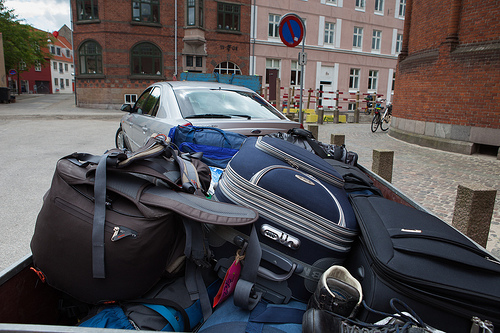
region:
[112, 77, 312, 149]
The gray vehicle in front of the bags.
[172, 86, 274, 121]
The back window of the vehicle.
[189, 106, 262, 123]
The windshield wiper on the back window of the vehicle.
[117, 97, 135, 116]
The side view mirror of the vehicle.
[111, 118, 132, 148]
The front tire of the vehicle.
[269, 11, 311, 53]
The circle sign to the right of the vehicle.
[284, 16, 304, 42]
The blue color within the circle street sign.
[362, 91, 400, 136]
The bicycle on the right.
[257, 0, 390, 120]
The light pink building.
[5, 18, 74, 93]
The red buildings in the distance.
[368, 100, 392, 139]
the parked bicycle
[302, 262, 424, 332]
the pair of shoes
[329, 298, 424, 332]
the shoe laces on the shoes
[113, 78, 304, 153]
the silver car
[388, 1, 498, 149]
the red brick building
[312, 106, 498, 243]
the stone sidewalk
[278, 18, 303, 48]
a red and blue circle sign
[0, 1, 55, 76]
the tree in the distance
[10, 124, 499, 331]
a pile of bags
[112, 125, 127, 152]
the front wheel on the car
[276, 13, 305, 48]
A blue and red sign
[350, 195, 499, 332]
A black suitcase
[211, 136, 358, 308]
A blue and grey suitcase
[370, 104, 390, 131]
A bicycle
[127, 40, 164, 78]
A green framed window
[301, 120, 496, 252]
A paved brick sidewalk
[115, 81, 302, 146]
A silver car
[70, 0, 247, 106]
A brick building with many windows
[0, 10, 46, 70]
A green leafy tree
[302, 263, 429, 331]
A pair of black shoes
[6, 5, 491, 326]
A city street scene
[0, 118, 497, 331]
A cart of luggage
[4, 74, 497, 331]
The car is pulling the cart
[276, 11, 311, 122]
A street sign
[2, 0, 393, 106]
Buildings are across the street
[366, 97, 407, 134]
A bicycle is next to the building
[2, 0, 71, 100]
A tree is growing near the building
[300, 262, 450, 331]
A pair of shoes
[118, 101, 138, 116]
The car's side view mirror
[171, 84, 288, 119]
The car's rear window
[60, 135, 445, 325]
Pile of luggage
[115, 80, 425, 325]
Silver car towing a cart of luggage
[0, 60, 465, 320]
Car towing a cart of luggage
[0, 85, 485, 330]
Silver car towing a cart piled with luggage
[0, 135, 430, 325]
Cart piled with luggage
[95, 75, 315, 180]
silver car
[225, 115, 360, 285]
Blue suitcase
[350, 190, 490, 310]
Black suitcase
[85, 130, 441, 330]
Pile of suitcases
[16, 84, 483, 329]
car towing luggage